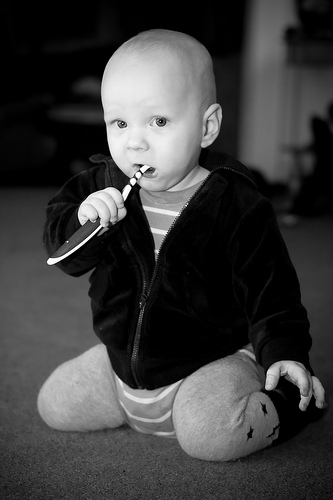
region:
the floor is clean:
[24, 441, 101, 480]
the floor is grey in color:
[30, 439, 129, 496]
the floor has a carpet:
[75, 459, 115, 489]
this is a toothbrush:
[45, 172, 174, 260]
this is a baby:
[39, 18, 325, 476]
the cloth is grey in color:
[192, 398, 220, 426]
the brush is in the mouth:
[39, 151, 173, 263]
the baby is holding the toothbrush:
[48, 151, 157, 283]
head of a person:
[95, 33, 233, 188]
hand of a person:
[73, 174, 141, 240]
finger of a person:
[80, 189, 138, 230]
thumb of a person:
[258, 353, 290, 392]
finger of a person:
[289, 371, 330, 417]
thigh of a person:
[159, 347, 266, 463]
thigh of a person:
[36, 334, 131, 432]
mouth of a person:
[125, 146, 170, 185]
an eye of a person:
[148, 110, 176, 134]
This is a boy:
[30, 21, 332, 423]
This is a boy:
[64, 26, 320, 455]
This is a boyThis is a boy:
[39, 17, 272, 493]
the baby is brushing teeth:
[54, 64, 244, 271]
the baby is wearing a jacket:
[36, 156, 283, 380]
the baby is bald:
[78, 51, 222, 207]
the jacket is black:
[32, 151, 296, 401]